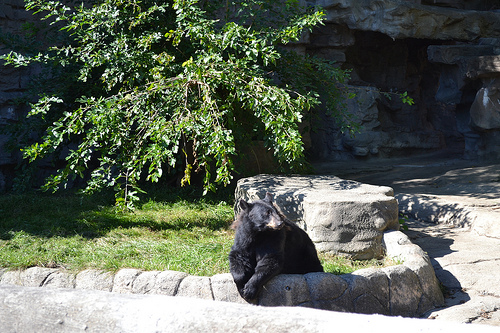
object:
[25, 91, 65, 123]
leaves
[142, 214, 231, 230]
shadow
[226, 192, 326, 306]
bear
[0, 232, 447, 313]
fence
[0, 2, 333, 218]
tree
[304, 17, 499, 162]
cave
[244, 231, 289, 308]
fore limbs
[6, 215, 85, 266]
grass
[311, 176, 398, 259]
rock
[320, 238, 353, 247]
ground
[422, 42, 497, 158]
rock wall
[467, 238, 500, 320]
sun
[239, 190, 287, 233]
head turned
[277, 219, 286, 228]
black nose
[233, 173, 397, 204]
platform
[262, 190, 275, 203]
ears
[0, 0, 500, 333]
zoo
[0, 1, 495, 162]
wall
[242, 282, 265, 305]
paws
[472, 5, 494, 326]
right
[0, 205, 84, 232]
shadow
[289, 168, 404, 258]
stone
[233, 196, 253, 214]
ear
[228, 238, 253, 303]
leg